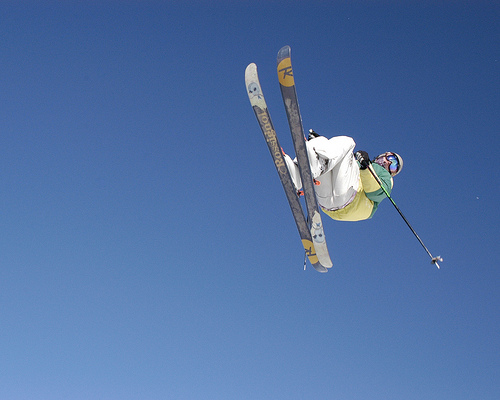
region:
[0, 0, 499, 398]
A very blue sky.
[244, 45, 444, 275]
A person on skies.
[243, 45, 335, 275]
A pair of skis.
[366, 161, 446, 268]
Black and green ski pole.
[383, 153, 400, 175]
A pair of ski goggles.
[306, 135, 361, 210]
A pair of ski pants.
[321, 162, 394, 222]
Yellow and green jacket.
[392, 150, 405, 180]
A white ski helmet.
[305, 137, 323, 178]
A white ski boot.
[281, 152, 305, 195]
A white colored ski boot.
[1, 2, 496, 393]
blue of daytime sky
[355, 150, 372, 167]
black glove on hand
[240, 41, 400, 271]
skier in mid air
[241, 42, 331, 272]
bottom of two skis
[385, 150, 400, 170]
helmet on skiers head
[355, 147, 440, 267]
gloved hand on ski pole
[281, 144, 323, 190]
white boots on feet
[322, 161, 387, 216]
green and yellow jacket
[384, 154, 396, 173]
goggles on skiers face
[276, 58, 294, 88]
letter in yellow circle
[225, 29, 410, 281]
skier doing tricks in air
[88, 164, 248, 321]
white clouds in blue sky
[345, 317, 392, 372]
white clouds in blue sky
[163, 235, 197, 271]
white clouds in blue sky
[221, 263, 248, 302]
white clouds in blue sky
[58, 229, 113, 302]
white clouds in blue sky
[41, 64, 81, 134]
white clouds in blue sky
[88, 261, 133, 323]
white clouds in blue sky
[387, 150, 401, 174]
goggles on skiers face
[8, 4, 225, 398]
the clear blue sky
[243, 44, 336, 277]
skis on the person's feet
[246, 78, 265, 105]
alien drawing on right ski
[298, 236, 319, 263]
yellow R on the ski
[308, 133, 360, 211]
white pants on the skier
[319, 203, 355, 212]
belt on the person's waist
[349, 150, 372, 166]
black glove on man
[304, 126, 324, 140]
black glove on man's right hand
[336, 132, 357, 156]
left knee of skier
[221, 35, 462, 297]
Person jumping on skis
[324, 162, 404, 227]
Yellow and green jacket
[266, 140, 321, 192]
White snow ski boots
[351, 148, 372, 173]
Person is wearing gloves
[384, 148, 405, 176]
Person is wearing ski goggles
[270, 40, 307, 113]
Ski has a yellow circle with gray letter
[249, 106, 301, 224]
Gray ski has white letters on it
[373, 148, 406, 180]
Wearing a ski mask under goggles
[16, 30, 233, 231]
Sky is clear blue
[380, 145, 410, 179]
Ski helmet and goggles